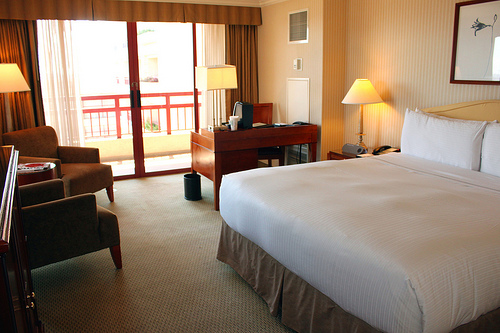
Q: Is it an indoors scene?
A: Yes, it is indoors.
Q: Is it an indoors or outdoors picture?
A: It is indoors.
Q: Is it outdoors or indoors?
A: It is indoors.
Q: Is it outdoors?
A: No, it is indoors.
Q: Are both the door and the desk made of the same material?
A: No, the door is made of glass and the desk is made of wood.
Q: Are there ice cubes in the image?
A: No, there are no ice cubes.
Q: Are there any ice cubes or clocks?
A: No, there are no ice cubes or clocks.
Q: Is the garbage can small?
A: Yes, the garbage can is small.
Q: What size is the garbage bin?
A: The garbage bin is small.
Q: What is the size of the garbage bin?
A: The garbage bin is small.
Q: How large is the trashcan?
A: The trashcan is small.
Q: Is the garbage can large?
A: No, the garbage can is small.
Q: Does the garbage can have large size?
A: No, the garbage can is small.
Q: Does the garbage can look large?
A: No, the garbage can is small.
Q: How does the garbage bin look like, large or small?
A: The garbage bin is small.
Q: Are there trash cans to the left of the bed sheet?
A: Yes, there is a trash can to the left of the bed sheet.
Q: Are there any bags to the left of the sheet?
A: No, there is a trash can to the left of the sheet.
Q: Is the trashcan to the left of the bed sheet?
A: Yes, the trashcan is to the left of the bed sheet.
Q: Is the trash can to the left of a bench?
A: No, the trash can is to the left of the bed sheet.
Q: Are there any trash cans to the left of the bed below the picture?
A: Yes, there is a trash can to the left of the bed.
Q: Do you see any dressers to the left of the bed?
A: No, there is a trash can to the left of the bed.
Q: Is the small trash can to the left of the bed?
A: Yes, the trashcan is to the left of the bed.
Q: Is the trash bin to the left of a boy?
A: No, the trash bin is to the left of the bed.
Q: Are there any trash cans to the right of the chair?
A: Yes, there is a trash can to the right of the chair.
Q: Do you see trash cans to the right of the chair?
A: Yes, there is a trash can to the right of the chair.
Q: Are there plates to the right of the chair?
A: No, there is a trash can to the right of the chair.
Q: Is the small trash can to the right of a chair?
A: Yes, the trashcan is to the right of a chair.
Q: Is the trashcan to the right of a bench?
A: No, the trashcan is to the right of a chair.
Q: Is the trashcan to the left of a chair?
A: No, the trashcan is to the right of a chair.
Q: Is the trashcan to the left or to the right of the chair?
A: The trashcan is to the right of the chair.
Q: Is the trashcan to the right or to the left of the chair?
A: The trashcan is to the right of the chair.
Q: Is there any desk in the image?
A: Yes, there is a desk.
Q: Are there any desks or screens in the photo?
A: Yes, there is a desk.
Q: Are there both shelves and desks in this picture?
A: No, there is a desk but no shelves.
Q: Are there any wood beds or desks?
A: Yes, there is a wood desk.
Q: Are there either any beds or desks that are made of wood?
A: Yes, the desk is made of wood.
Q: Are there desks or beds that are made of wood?
A: Yes, the desk is made of wood.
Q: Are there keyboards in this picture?
A: No, there are no keyboards.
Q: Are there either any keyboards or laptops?
A: No, there are no keyboards or laptops.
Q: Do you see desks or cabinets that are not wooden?
A: No, there is a desk but it is wooden.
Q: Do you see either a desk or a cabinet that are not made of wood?
A: No, there is a desk but it is made of wood.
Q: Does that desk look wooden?
A: Yes, the desk is wooden.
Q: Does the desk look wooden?
A: Yes, the desk is wooden.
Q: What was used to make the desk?
A: The desk is made of wood.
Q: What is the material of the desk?
A: The desk is made of wood.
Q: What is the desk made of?
A: The desk is made of wood.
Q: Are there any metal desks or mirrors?
A: No, there is a desk but it is wooden.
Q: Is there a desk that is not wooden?
A: No, there is a desk but it is wooden.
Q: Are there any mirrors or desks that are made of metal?
A: No, there is a desk but it is made of wood.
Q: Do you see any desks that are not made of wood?
A: No, there is a desk but it is made of wood.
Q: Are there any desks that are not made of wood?
A: No, there is a desk but it is made of wood.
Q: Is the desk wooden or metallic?
A: The desk is wooden.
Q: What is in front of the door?
A: The desk is in front of the door.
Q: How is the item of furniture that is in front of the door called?
A: The piece of furniture is a desk.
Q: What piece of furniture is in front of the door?
A: The piece of furniture is a desk.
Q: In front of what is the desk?
A: The desk is in front of the door.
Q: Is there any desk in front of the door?
A: Yes, there is a desk in front of the door.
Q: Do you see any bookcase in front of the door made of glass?
A: No, there is a desk in front of the door.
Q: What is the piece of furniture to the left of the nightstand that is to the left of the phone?
A: The piece of furniture is a desk.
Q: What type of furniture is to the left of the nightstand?
A: The piece of furniture is a desk.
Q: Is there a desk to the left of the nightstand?
A: Yes, there is a desk to the left of the nightstand.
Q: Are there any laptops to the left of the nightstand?
A: No, there is a desk to the left of the nightstand.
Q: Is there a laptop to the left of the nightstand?
A: No, there is a desk to the left of the nightstand.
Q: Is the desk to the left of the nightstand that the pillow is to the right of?
A: Yes, the desk is to the left of the nightstand.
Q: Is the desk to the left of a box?
A: No, the desk is to the left of the nightstand.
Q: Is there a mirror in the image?
A: No, there are no mirrors.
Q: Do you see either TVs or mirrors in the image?
A: No, there are no mirrors or tvs.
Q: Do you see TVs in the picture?
A: No, there are no tvs.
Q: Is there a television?
A: No, there are no televisions.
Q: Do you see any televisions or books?
A: No, there are no televisions or books.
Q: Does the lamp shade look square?
A: Yes, the lamp shade is square.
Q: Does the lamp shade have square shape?
A: Yes, the lamp shade is square.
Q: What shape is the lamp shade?
A: The lamp shade is square.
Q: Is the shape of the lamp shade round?
A: No, the lamp shade is square.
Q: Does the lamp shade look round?
A: No, the lamp shade is square.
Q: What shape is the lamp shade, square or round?
A: The lamp shade is square.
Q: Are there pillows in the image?
A: Yes, there is a pillow.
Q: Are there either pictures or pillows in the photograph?
A: Yes, there is a pillow.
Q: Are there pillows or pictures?
A: Yes, there is a pillow.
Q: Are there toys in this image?
A: No, there are no toys.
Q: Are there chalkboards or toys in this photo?
A: No, there are no toys or chalkboards.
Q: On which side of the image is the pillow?
A: The pillow is on the right of the image.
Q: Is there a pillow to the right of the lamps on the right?
A: Yes, there is a pillow to the right of the lamps.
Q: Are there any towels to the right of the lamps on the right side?
A: No, there is a pillow to the right of the lamps.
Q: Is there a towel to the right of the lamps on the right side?
A: No, there is a pillow to the right of the lamps.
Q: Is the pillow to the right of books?
A: No, the pillow is to the right of the lamps.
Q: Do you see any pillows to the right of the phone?
A: Yes, there is a pillow to the right of the phone.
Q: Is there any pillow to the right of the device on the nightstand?
A: Yes, there is a pillow to the right of the phone.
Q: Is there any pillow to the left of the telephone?
A: No, the pillow is to the right of the telephone.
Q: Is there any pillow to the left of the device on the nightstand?
A: No, the pillow is to the right of the telephone.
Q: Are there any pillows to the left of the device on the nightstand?
A: No, the pillow is to the right of the telephone.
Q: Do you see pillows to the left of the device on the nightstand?
A: No, the pillow is to the right of the telephone.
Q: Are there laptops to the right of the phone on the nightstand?
A: No, there is a pillow to the right of the phone.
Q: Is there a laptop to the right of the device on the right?
A: No, there is a pillow to the right of the phone.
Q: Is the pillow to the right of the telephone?
A: Yes, the pillow is to the right of the telephone.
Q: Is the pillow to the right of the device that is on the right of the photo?
A: Yes, the pillow is to the right of the telephone.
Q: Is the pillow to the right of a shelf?
A: No, the pillow is to the right of the telephone.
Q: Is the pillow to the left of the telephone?
A: No, the pillow is to the right of the telephone.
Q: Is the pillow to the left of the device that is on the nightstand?
A: No, the pillow is to the right of the telephone.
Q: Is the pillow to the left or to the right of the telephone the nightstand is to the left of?
A: The pillow is to the right of the phone.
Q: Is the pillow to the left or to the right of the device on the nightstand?
A: The pillow is to the right of the phone.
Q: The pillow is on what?
A: The pillow is on the bed.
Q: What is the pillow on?
A: The pillow is on the bed.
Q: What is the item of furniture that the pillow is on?
A: The piece of furniture is a bed.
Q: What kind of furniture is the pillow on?
A: The pillow is on the bed.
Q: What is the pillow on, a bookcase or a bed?
A: The pillow is on a bed.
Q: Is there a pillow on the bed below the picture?
A: Yes, there is a pillow on the bed.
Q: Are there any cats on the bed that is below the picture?
A: No, there is a pillow on the bed.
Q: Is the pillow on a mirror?
A: No, the pillow is on the bed.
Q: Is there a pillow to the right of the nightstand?
A: Yes, there is a pillow to the right of the nightstand.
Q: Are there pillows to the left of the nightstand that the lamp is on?
A: No, the pillow is to the right of the nightstand.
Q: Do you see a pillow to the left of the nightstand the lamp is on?
A: No, the pillow is to the right of the nightstand.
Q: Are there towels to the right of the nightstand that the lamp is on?
A: No, there is a pillow to the right of the nightstand.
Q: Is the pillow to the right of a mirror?
A: No, the pillow is to the right of the nightstand.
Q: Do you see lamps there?
A: Yes, there is a lamp.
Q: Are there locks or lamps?
A: Yes, there is a lamp.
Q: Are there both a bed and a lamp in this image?
A: Yes, there are both a lamp and a bed.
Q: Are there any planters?
A: No, there are no planters.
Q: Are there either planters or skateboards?
A: No, there are no planters or skateboards.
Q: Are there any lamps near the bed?
A: Yes, there is a lamp near the bed.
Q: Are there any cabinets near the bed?
A: No, there is a lamp near the bed.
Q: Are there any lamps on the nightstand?
A: Yes, there is a lamp on the nightstand.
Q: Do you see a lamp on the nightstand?
A: Yes, there is a lamp on the nightstand.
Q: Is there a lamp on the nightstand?
A: Yes, there is a lamp on the nightstand.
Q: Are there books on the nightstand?
A: No, there is a lamp on the nightstand.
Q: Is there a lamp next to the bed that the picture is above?
A: Yes, there is a lamp next to the bed.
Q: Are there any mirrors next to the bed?
A: No, there is a lamp next to the bed.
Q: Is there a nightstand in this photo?
A: Yes, there is a nightstand.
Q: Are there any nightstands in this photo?
A: Yes, there is a nightstand.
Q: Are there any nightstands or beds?
A: Yes, there is a nightstand.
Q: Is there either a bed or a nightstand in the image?
A: Yes, there is a nightstand.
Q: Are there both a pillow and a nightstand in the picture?
A: Yes, there are both a nightstand and a pillow.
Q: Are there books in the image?
A: No, there are no books.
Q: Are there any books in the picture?
A: No, there are no books.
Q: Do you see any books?
A: No, there are no books.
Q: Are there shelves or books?
A: No, there are no books or shelves.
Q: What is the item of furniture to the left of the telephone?
A: The piece of furniture is a nightstand.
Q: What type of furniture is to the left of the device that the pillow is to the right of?
A: The piece of furniture is a nightstand.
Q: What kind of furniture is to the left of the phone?
A: The piece of furniture is a nightstand.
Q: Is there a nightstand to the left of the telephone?
A: Yes, there is a nightstand to the left of the telephone.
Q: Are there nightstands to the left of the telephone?
A: Yes, there is a nightstand to the left of the telephone.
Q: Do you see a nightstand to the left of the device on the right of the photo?
A: Yes, there is a nightstand to the left of the telephone.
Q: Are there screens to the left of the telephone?
A: No, there is a nightstand to the left of the telephone.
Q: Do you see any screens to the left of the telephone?
A: No, there is a nightstand to the left of the telephone.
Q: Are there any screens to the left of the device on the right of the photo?
A: No, there is a nightstand to the left of the telephone.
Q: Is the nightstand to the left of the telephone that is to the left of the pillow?
A: Yes, the nightstand is to the left of the phone.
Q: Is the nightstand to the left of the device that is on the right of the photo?
A: Yes, the nightstand is to the left of the phone.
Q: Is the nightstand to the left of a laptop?
A: No, the nightstand is to the left of the phone.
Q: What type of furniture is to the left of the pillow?
A: The piece of furniture is a nightstand.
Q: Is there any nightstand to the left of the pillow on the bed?
A: Yes, there is a nightstand to the left of the pillow.